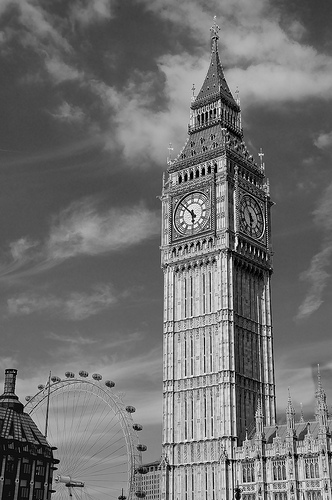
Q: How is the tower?
A: Has a clock on each side.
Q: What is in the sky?
A: Clouds.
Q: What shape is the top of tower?
A: Triangle.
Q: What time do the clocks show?
A: 5:43.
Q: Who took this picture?
A: A tourist.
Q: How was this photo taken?
A: With wide lense.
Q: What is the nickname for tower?
A: Big Ben.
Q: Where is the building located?
A: London.